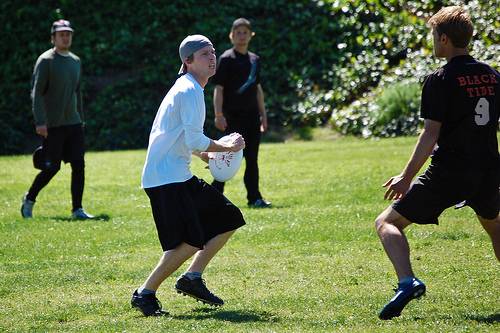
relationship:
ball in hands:
[210, 137, 244, 183] [201, 133, 246, 164]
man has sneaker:
[127, 33, 248, 318] [173, 274, 226, 308]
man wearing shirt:
[20, 18, 96, 219] [32, 48, 88, 126]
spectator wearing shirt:
[212, 17, 269, 206] [212, 49, 262, 121]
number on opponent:
[474, 97, 489, 128] [373, 7, 499, 321]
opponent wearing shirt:
[373, 7, 499, 321] [419, 56, 499, 169]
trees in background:
[0, 2, 499, 153] [0, 0, 499, 169]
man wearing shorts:
[127, 33, 248, 318] [143, 175, 246, 251]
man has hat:
[127, 33, 248, 318] [177, 33, 215, 77]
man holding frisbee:
[127, 33, 248, 318] [207, 137, 242, 183]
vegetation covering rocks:
[1, 1, 498, 148] [75, 60, 141, 106]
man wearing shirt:
[127, 33, 248, 318] [140, 75, 212, 189]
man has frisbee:
[127, 33, 248, 318] [207, 137, 242, 183]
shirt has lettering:
[419, 56, 499, 169] [457, 72, 498, 97]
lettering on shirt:
[457, 72, 498, 97] [419, 56, 499, 169]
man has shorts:
[127, 33, 248, 318] [143, 175, 246, 251]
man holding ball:
[127, 33, 248, 318] [210, 137, 244, 183]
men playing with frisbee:
[20, 6, 498, 322] [207, 137, 242, 183]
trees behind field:
[0, 2, 499, 153] [0, 128, 496, 333]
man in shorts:
[127, 33, 248, 318] [143, 175, 246, 251]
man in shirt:
[127, 33, 248, 318] [140, 75, 212, 189]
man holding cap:
[20, 18, 96, 219] [32, 136, 50, 173]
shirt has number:
[419, 56, 499, 169] [474, 97, 489, 128]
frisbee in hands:
[207, 137, 242, 183] [201, 133, 246, 164]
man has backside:
[127, 33, 248, 318] [140, 72, 183, 194]